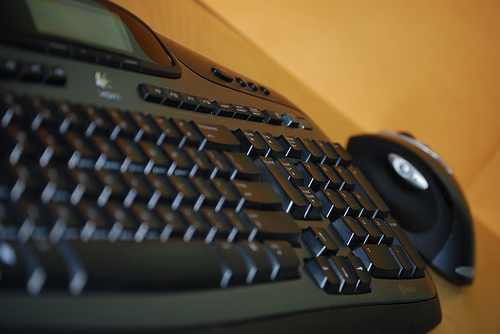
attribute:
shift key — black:
[233, 205, 304, 237]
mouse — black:
[344, 124, 497, 277]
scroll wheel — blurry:
[398, 130, 415, 140]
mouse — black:
[346, 131, 473, 286]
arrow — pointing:
[340, 264, 350, 281]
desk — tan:
[162, 2, 489, 318]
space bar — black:
[76, 227, 234, 299]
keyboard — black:
[31, 83, 479, 294]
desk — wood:
[112, 0, 497, 332]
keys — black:
[73, 99, 108, 139]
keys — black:
[118, 136, 149, 174]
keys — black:
[147, 170, 176, 204]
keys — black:
[220, 207, 250, 240]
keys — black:
[218, 239, 246, 289]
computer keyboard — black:
[17, 13, 444, 304]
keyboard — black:
[5, 3, 444, 325]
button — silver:
[385, 149, 428, 191]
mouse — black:
[347, 102, 489, 267]